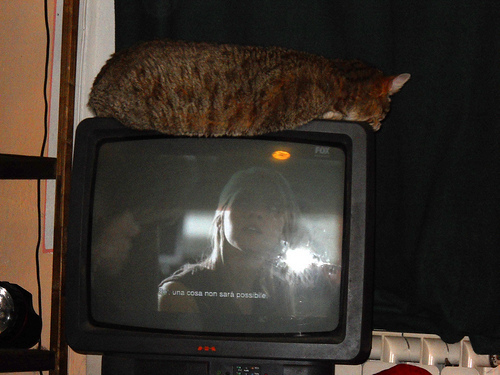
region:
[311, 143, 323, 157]
white letter on television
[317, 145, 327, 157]
white letter on television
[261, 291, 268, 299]
white letter on television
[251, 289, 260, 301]
white letter on television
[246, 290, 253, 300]
white letter on television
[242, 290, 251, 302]
white letter on television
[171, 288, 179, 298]
white letter on television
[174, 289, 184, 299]
white letter on television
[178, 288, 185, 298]
white letter on television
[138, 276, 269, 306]
closed caption on television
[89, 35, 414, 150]
cat with a brown coat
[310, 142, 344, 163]
fox symbol on TV program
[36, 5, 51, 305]
cord draped down the wall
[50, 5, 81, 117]
part of wood trim around window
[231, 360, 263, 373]
controls for the television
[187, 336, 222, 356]
three red dots on front of TV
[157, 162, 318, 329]
girl on a TV program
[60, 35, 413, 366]
cat laying on top of TV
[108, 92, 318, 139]
cats big belly laying of top tv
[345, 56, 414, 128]
cats headfacing back of TV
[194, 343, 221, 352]
three red dots on front of TV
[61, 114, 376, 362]
black TV on top of table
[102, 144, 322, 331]
woman in the TV screen looking up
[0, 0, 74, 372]
shelves on the wall behind TV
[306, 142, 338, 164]
tv channel log in top corner of screen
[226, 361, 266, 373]
outlets on tv for output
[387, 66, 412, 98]
cats ears sitting on TV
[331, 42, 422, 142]
head of a cat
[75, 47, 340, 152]
body of a cat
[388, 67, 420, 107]
an ear of a cat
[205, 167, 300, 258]
head of a person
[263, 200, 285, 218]
eye of a person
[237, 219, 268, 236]
mouth of a person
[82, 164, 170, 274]
head of a person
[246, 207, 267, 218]
nose of a person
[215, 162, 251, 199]
hair of a person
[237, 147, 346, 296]
reflections from the tv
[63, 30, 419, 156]
the cat is on the tv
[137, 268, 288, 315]
these are subtitles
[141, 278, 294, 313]
the subtitles are white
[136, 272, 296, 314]
the subtitles are in spanish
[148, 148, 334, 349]
a woman in the tv screen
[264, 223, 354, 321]
this light is from a camera flash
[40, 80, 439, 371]
an old television set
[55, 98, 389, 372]
a black tv set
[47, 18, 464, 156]
the cat is asleep on the tv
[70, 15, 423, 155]
a grey cat lying on a tv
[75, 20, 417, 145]
cat asleep on top of TV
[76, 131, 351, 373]
old TV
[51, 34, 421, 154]
cat with stripes on TV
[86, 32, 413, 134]
a large brown and black cat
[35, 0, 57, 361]
a long black cord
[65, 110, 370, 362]
a small black t.v.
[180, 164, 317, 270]
a woman's blonde hair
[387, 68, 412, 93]
the ear of a cat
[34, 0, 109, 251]
a white window trim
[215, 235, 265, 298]
the neck of a woman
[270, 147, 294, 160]
an orange light reflection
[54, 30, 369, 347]
the tv is on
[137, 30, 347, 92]
the cat is laying down